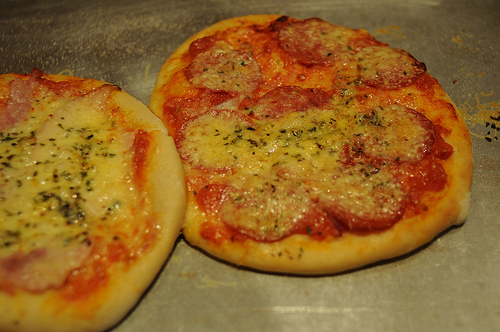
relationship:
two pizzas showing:
[0, 22, 491, 326] [145, 21, 494, 277]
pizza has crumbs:
[145, 21, 494, 277] [456, 71, 495, 110]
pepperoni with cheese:
[145, 21, 494, 277] [188, 49, 427, 227]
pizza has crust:
[145, 21, 494, 277] [126, 66, 191, 224]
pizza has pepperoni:
[145, 21, 494, 277] [198, 46, 258, 90]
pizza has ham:
[145, 21, 494, 277] [10, 69, 140, 155]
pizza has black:
[145, 21, 494, 277] [479, 111, 498, 127]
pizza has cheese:
[145, 21, 494, 277] [188, 49, 427, 227]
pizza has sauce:
[145, 21, 494, 277] [430, 120, 443, 177]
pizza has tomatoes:
[145, 21, 494, 277] [193, 33, 236, 53]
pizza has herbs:
[145, 21, 494, 277] [25, 120, 106, 172]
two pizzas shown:
[0, 22, 491, 326] [145, 21, 494, 277]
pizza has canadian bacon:
[145, 21, 494, 277] [305, 156, 401, 232]